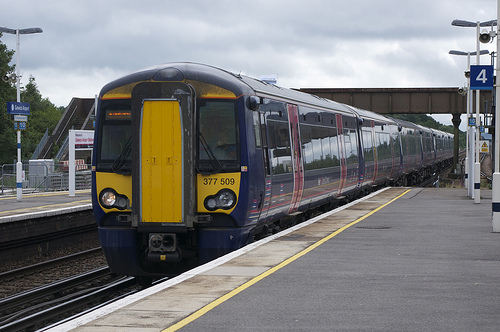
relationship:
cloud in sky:
[0, 0, 499, 107] [1, 0, 497, 130]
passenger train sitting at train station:
[66, 55, 457, 292] [97, 13, 474, 329]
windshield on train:
[197, 97, 242, 171] [87, 59, 457, 275]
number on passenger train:
[217, 174, 237, 186] [89, 59, 458, 289]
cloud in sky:
[67, 14, 268, 70] [1, 0, 497, 130]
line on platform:
[166, 187, 411, 330] [39, 182, 496, 329]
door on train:
[131, 91, 196, 225] [77, 46, 465, 288]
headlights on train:
[98, 187, 237, 212] [87, 59, 457, 275]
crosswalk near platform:
[304, 189, 484, 319] [377, 175, 489, 313]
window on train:
[259, 106, 459, 173] [87, 59, 457, 275]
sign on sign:
[12, 114, 31, 123] [7, 101, 34, 116]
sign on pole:
[7, 101, 34, 116] [12, 136, 29, 200]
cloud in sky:
[0, 0, 499, 107] [262, 11, 478, 92]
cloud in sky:
[0, 0, 499, 107] [254, 4, 484, 82]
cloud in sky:
[0, 0, 499, 107] [0, 2, 496, 117]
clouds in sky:
[283, 22, 345, 66] [0, 2, 496, 117]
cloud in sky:
[0, 0, 499, 107] [130, 6, 482, 72]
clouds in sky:
[321, 32, 403, 73] [10, 0, 494, 91]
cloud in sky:
[0, 0, 499, 107] [29, 3, 489, 85]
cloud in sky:
[0, 0, 499, 107] [92, 5, 483, 88]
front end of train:
[88, 59, 256, 277] [87, 59, 457, 275]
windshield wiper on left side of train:
[198, 131, 222, 173] [64, 59, 469, 253]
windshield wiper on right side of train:
[195, 126, 225, 174] [87, 59, 457, 275]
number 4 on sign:
[474, 67, 488, 82] [468, 62, 494, 89]